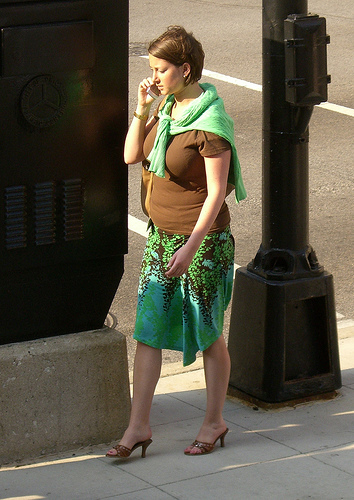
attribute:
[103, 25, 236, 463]
woman — skirt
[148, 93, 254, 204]
sweater — green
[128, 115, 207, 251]
teeshirt — brown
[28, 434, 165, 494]
sidewalk — paved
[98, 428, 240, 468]
sandals — brown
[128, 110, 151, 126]
watch — gold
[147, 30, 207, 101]
hair — brown, short